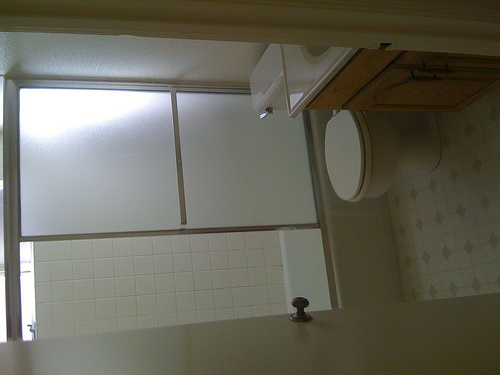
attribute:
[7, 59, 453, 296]
window — window pane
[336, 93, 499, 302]
flooring — decorative, tiled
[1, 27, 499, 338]
bathroom — lit up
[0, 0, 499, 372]
photo — indoors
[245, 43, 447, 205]
toilet — White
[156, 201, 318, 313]
wall — tiled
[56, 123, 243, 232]
door — shower door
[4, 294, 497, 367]
door — White, black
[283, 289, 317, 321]
handle — metalic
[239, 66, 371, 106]
sink — white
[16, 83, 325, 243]
door — shower door, transparent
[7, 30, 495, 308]
bathroom — small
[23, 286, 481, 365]
door — white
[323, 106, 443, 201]
toilet — white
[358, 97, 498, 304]
pattern — Diamond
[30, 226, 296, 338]
tile — white